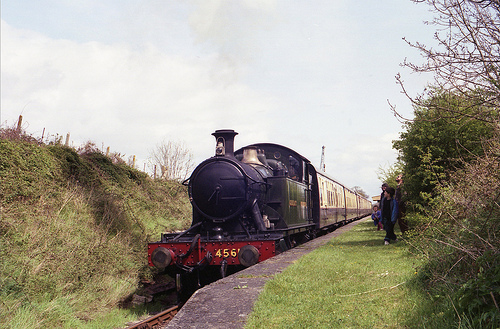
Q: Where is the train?
A: On the tracks.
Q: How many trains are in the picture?
A: One.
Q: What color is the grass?
A: Green.